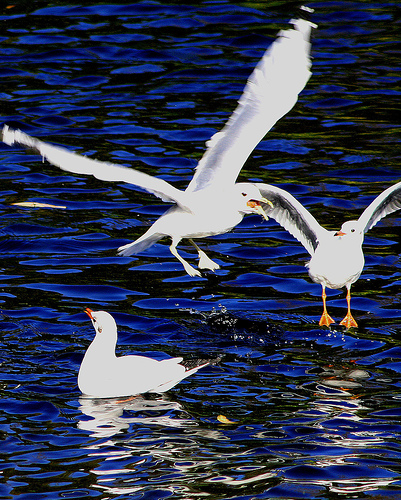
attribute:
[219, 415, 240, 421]
leaf — big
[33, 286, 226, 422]
seagull — walking, three, wing, floating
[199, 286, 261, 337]
water — splash, ripple, calm, dark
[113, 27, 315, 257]
bird — about, attcking, extended, open, floating, white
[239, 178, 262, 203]
eye — black, small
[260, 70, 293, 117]
feather — white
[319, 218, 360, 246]
beak — orange